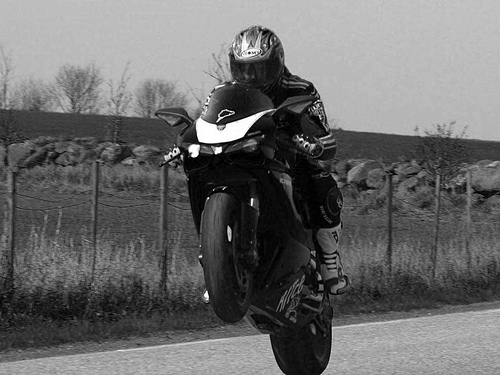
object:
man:
[167, 27, 346, 294]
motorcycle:
[153, 81, 337, 375]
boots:
[309, 221, 349, 294]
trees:
[408, 116, 470, 199]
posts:
[2, 163, 16, 293]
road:
[1, 299, 499, 374]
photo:
[2, 2, 498, 371]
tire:
[198, 192, 258, 324]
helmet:
[227, 25, 285, 80]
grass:
[22, 322, 49, 339]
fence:
[7, 159, 500, 279]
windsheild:
[196, 88, 272, 143]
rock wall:
[6, 136, 145, 174]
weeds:
[10, 261, 28, 300]